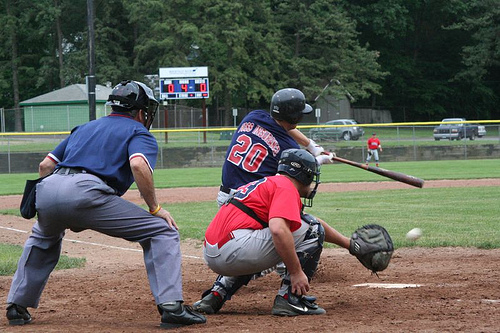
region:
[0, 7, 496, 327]
Men playing baseball.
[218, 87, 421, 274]
Batter is swinging and missing the ball.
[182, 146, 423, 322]
Catcher is catching the ball.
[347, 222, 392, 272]
Catcher is wearing a black baseball glove.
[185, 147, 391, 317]
Catcher is squatting down.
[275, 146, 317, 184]
Catcher is wearing a black helmet.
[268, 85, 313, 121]
Batter is wearing a black helmet.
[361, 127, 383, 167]
Man standing in the field.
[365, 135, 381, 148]
Man is wearing a red shirt.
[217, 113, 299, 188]
Batter is wearing a blue shirt.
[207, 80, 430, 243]
a batter swinging his bat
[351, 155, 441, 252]
a baseball going under a bat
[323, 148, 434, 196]
a dark brown wooden bat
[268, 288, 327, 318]
a baseball shoe with the Nike logo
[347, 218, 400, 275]
a black baseball catcher's mitt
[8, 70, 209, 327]
the umpire at a baseball game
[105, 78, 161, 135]
the umpire's black helmet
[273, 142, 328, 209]
a catcher's black helmet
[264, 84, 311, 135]
a black batter's helmet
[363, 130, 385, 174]
an outfield on a baseball field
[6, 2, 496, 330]
a baseball game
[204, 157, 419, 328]
the catcher is catching the ball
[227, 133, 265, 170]
the number 20 om the player the uniform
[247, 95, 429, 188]
baseball player swinging his bat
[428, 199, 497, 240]
some grass in the field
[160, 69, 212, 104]
the score board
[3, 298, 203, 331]
a pair of black sneakers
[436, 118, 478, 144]
a pick up vehicle in the distance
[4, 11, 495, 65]
a dense forest in the background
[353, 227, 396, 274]
the catcher glove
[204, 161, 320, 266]
the shirt is red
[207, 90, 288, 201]
jersey number is 20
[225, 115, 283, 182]
jersey number is 20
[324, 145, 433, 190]
baseball bat in the guy's hand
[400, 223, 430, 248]
blurry white baseball on the grass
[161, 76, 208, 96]
scoreboard above the fence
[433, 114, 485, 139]
black truck on the road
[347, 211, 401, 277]
black mitt on the hand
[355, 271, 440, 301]
white base in the dirt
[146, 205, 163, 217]
yellow band on the wrist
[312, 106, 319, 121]
sign on a pole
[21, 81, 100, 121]
green building with roof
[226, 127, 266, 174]
number 20 on the shirt